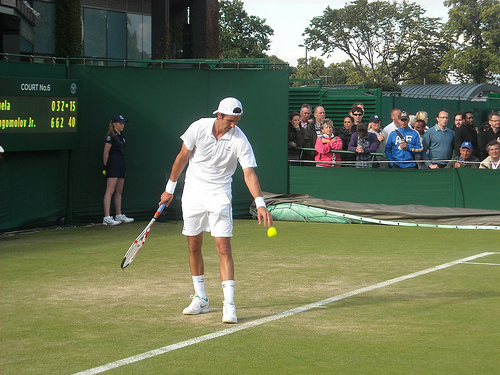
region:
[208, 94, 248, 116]
white hat on a tennis player's head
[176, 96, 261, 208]
white shirt on a tennis player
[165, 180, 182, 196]
white band on a player's wrist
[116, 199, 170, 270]
white red and blue tennis racket in a player's hand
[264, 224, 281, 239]
green tennis bal in the air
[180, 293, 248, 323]
white shoes on the player's feet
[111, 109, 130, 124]
dark colored hat on the woman's head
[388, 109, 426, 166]
man wearing a blue jacket and a hat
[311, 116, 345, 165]
woman wearing a pink coat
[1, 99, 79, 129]
digital text on a black display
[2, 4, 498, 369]
a tennis game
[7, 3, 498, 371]
a tennis match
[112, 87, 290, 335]
a man playing tennis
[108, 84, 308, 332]
the man is serving the tennis ball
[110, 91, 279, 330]
the man holds the racket in his right hand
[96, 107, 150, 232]
a woman in black stands in the corner of the court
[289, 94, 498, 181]
spectators watch the match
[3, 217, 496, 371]
the tennis court has a grass surface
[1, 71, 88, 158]
a scoreboard on the wall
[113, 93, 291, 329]
the tennis player is wearing white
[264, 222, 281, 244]
The ball is yellow.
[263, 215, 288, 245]
The ball is round.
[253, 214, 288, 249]
The ball is airborne.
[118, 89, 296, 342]
The man is standing.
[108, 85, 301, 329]
Man is wearing cap.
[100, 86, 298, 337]
Man's cap is white.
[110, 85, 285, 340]
The cap is backwards.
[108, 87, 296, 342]
Man is holding racket.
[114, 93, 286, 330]
Man is wearing shorts.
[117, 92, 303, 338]
man serving tennis ball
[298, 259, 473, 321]
white markings on tennis court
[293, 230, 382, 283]
grass on tennis court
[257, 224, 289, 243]
yellow tennis ball in mid air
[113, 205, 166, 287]
orange, white and black tennis rachet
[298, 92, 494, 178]
crowd watching tennis match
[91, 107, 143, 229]
ball girl on sidelines of court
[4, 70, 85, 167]
electronic score board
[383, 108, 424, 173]
man in blue jacket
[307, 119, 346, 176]
woman dressed in pink jacket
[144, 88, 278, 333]
Man wearing all white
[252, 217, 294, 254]
Green ball in air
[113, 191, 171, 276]
Tennis racket in man's hand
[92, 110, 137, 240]
Woman standing near wall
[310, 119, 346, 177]
Woman wearing pink jacket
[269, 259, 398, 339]
White line on grass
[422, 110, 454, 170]
Man wearing a green sweater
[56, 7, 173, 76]
Glass doors above green wall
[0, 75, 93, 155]
Scoreboard on the wall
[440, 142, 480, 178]
Man wearing a blue hat